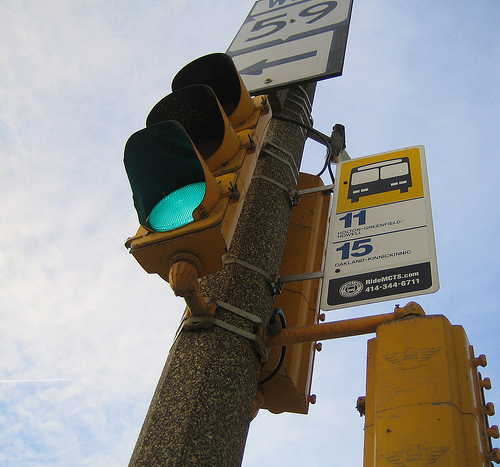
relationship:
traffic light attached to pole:
[99, 52, 282, 312] [125, 344, 275, 465]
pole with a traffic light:
[125, 344, 275, 465] [99, 52, 282, 312]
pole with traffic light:
[125, 344, 275, 465] [99, 52, 282, 312]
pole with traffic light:
[130, 82, 331, 467] [99, 52, 282, 312]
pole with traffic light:
[125, 344, 275, 465] [123, 53, 274, 316]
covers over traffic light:
[123, 119, 217, 231] [99, 52, 282, 312]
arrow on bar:
[238, 50, 317, 75] [285, 183, 334, 195]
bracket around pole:
[224, 253, 272, 281] [125, 344, 275, 465]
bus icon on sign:
[343, 152, 420, 208] [318, 143, 438, 311]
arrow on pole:
[238, 50, 317, 75] [130, 82, 331, 467]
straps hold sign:
[225, 173, 285, 286] [318, 143, 438, 311]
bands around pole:
[181, 300, 270, 359] [125, 344, 275, 465]